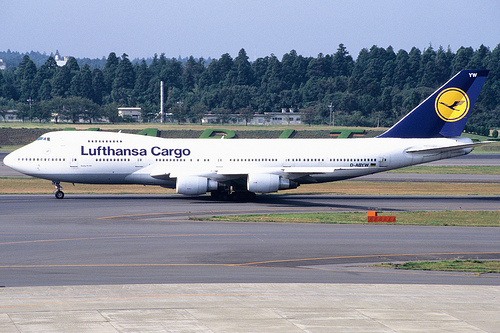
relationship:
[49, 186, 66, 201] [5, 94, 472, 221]
wheel on plane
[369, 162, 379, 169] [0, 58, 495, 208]
flag on plane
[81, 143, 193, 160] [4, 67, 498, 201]
letters on plane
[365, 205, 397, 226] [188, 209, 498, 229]
object in grass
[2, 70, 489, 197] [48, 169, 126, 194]
plane has wheel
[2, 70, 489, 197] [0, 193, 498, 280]
plane on runway